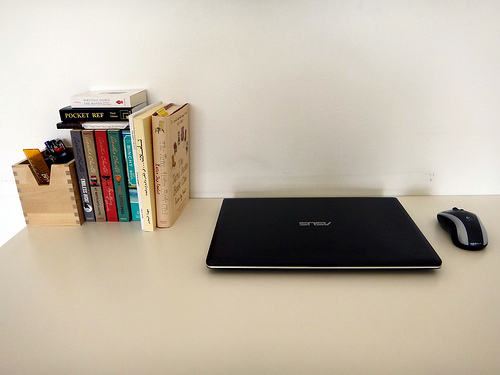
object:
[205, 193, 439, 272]
laptop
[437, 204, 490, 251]
mouse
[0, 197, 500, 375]
table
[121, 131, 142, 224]
books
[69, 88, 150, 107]
book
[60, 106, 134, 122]
book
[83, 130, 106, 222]
book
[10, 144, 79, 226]
desk container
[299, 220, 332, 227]
asus logo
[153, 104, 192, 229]
book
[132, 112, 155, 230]
book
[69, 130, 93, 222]
book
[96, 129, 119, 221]
book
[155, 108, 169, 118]
bookmark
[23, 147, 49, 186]
ruler